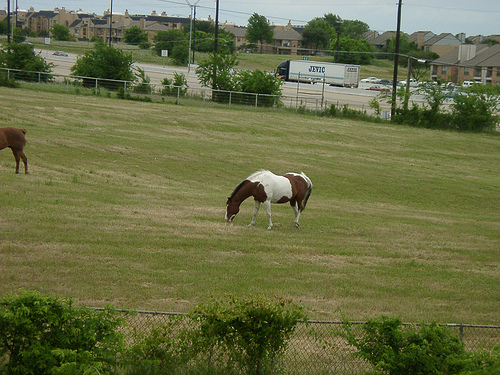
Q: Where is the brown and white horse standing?
A: In a field.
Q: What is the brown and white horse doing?
A: Eating grass.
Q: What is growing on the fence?
A: Green plants.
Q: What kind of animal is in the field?
A: Horses.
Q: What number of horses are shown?
A: 2.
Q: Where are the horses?
A: In a field.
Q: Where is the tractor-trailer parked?
A: In the parking lot.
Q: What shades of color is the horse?
A: Brown and white.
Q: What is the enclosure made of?
A: Fence.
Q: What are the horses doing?
A: Grazing.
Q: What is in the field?
A: A horse.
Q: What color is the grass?
A: Green.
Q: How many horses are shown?
A: Two.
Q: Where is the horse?
A: In the field.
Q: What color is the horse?
A: Brown and white.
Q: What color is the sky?
A: Blue.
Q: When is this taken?
A: During the day.